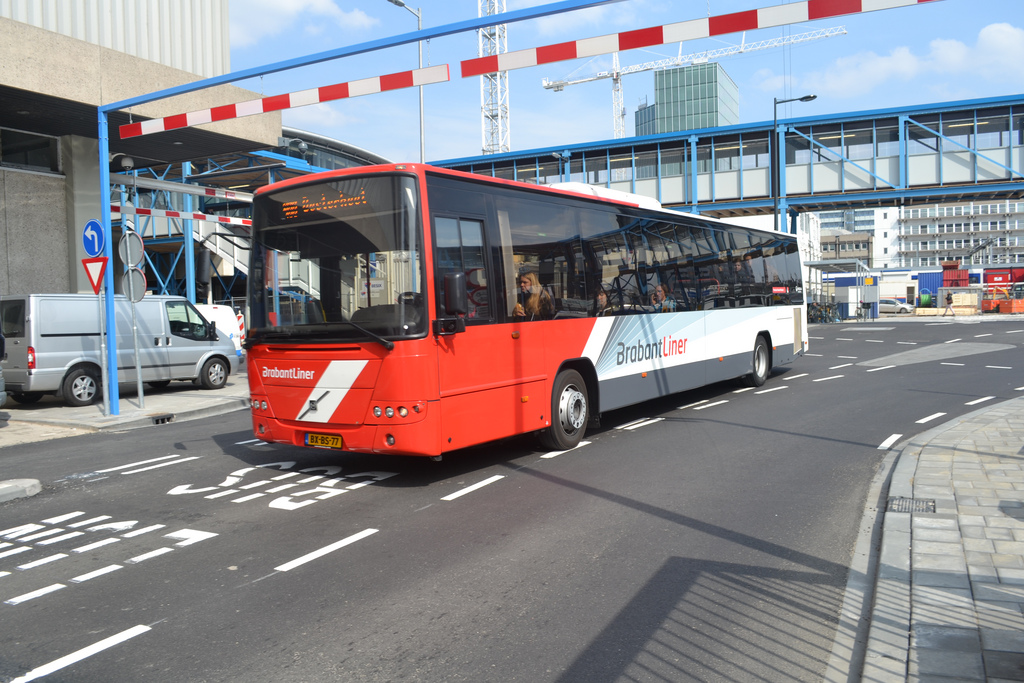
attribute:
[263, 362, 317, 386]
lettering — white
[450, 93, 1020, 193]
overpass — blue, pedestrian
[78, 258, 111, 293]
sign — red, white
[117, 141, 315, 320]
scaffolding — blue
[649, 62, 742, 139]
building — tall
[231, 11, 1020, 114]
sky — blue , cloudy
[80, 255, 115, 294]
sign — red, white, triangular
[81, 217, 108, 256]
sign — round, blue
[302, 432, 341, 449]
plate — yellow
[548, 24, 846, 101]
crane — white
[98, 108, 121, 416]
pole — blue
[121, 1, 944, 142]
stripedboards — white, red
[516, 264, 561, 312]
woman — blond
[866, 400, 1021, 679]
sidewalk — paved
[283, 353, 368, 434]
design — white 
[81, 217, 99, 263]
arrow — white